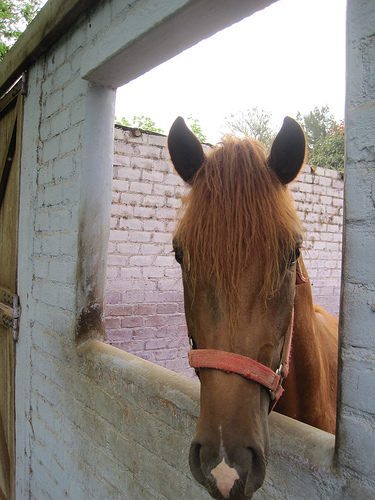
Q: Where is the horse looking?
A: At the camera.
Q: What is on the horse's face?
A: Bridle.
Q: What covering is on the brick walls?
A: White paint.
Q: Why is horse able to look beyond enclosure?
A: Opening in wall.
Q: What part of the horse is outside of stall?
A: Head.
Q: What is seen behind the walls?
A: Trees.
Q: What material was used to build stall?
A: Brick.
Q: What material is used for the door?
A: Wood.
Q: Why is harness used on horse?
A: For control.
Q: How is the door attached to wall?
A: Hinge.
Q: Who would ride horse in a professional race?
A: Jockey.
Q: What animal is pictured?
A: Horse.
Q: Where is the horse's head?
A: Window of a brick stall.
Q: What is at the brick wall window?
A: A brown horse head.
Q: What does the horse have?
A: It has a red bridle.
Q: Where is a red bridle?
A: It is on a horse.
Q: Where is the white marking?
A: It is on horse.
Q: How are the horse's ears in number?
A: Two ears.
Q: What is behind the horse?
A: Green trees.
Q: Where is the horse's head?
A: It is through a brick window building.